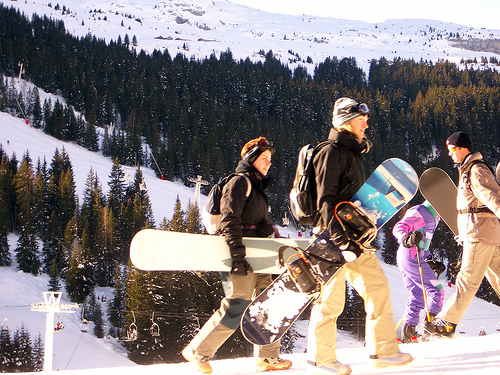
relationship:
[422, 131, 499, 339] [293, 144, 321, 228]
man wearing backpack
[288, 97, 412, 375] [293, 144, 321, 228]
man wearing backpack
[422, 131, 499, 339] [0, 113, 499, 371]
man walking on snow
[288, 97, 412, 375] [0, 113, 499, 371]
man walking on snow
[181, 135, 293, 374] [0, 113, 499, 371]
lady walking on snow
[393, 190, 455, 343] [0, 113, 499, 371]
people walking on snow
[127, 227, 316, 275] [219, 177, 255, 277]
snowboard under arm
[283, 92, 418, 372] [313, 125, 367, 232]
man wearing jacket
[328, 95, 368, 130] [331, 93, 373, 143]
hat on head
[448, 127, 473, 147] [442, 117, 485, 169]
hat on man's head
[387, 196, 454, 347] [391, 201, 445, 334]
girl wearing snowsuit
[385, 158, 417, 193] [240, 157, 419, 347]
blue stripe on snowboard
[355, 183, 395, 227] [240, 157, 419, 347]
blue stripe on snowboard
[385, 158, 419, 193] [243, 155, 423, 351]
blue stripe on back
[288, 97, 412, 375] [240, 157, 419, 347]
man carrying snowboard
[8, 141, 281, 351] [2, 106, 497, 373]
trees on ski slope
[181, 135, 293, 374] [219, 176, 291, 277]
lady wearing a ski jacket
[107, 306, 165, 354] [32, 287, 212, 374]
skiers riding up mountain on a ski lift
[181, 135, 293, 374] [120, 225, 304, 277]
lady carrying snowboard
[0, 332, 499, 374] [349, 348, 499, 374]
ground has shadow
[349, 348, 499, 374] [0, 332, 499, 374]
shadow on ground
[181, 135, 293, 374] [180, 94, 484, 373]
lady in group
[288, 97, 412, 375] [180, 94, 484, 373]
man in group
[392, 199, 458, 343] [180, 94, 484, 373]
people in group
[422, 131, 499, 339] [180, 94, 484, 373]
man in group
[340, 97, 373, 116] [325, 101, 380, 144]
goggles on hat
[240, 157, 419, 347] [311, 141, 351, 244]
snowboard under arm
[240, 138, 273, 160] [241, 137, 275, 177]
headband on woman's head